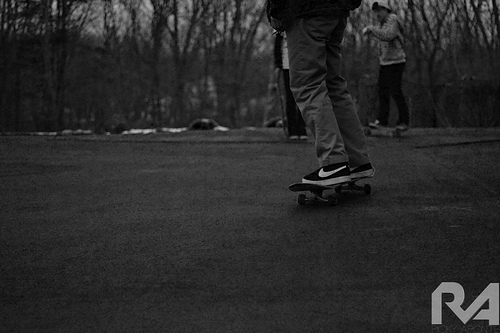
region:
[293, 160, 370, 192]
a white logo on the shoe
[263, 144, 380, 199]
a white logo on the shoe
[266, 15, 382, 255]
a person riding a skateboard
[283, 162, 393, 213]
Black skateboard on the pavement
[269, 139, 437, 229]
Black and white shoes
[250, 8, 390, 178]
Kakki colored pants on man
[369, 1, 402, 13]
Man wearing a white hat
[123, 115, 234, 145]
Snow covering the ground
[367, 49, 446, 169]
PErson riding a skateboard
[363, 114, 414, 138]
Black and white shoes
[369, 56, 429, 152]
PErson wearing black pants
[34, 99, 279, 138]
Snow covering the ground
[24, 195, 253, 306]
PArt of the pavement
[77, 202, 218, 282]
black surface on the ground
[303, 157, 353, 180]
white swoosh on sneakers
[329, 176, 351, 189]
white bottom on sneakers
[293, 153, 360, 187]
black and white sneakers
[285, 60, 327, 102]
wrinkles in gray pants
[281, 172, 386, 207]
skate board under man's foot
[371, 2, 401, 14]
cap on man's head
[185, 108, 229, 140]
car parked on side of the road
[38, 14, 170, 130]
tall bare trees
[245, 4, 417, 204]
men on sidewalk standing on skates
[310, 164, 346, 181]
white check on a sneaker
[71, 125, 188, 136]
snow on the ground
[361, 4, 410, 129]
a boy on skateboard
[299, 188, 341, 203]
wheels on the skateboard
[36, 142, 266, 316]
gray asphalt on the ground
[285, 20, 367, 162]
pants covering legs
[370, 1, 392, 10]
a cap on a head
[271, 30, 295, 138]
a person holding a skateboard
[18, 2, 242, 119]
trees behind the person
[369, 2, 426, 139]
a person wearing dark pants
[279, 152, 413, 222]
skateboard on the ground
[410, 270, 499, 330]
writing in bottom left corner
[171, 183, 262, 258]
street under the board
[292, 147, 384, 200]
shoes of the skater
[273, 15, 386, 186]
pants of the person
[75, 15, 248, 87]
many trees in the background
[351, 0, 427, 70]
kid in the background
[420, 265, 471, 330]
the letter R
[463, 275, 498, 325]
The letter A in bottom right corner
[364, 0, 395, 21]
boy wearing a hat